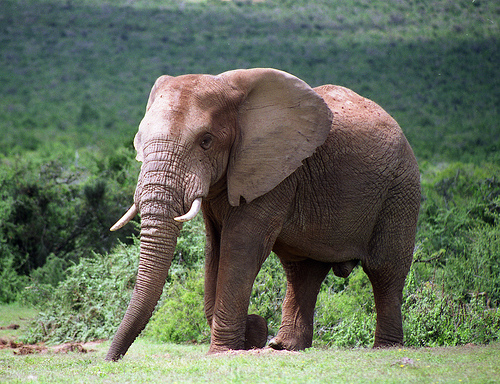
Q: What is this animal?
A: Elephant.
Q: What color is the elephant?
A: Brown.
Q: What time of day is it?
A: Daytime.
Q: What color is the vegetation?
A: Green.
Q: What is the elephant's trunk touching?
A: The ground.